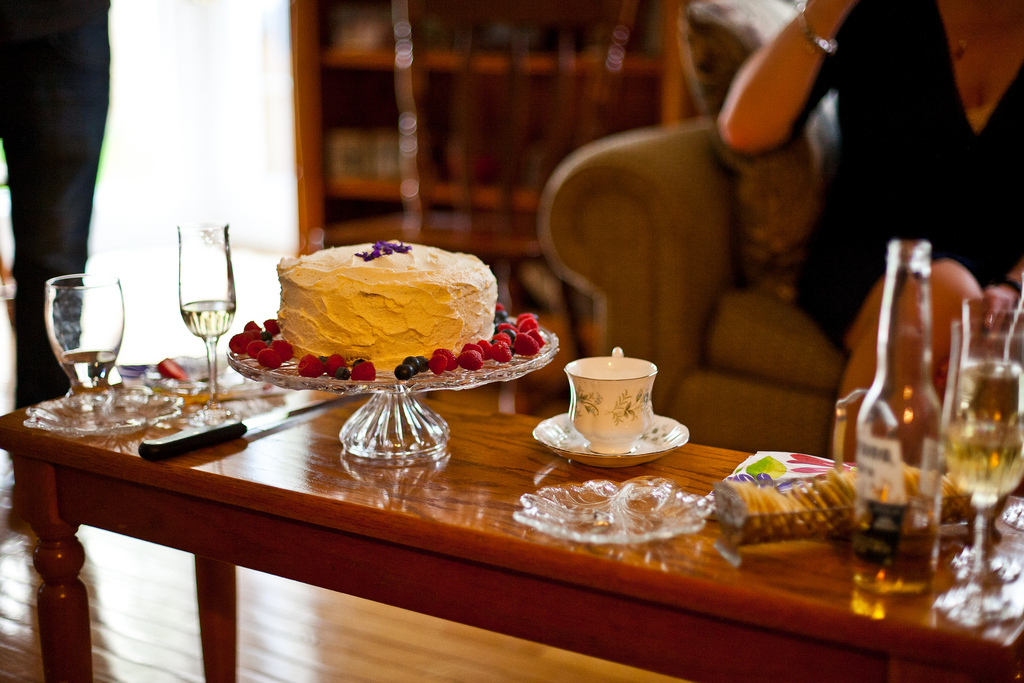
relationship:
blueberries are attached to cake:
[353, 239, 411, 263] [219, 217, 520, 390]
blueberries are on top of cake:
[353, 239, 411, 263] [219, 217, 520, 390]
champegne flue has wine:
[176, 220, 242, 430] [169, 278, 250, 356]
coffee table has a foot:
[0, 377, 1024, 683] [4, 410, 108, 678]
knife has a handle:
[139, 393, 375, 463] [141, 410, 256, 477]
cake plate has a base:
[220, 293, 571, 479] [311, 388, 487, 479]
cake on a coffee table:
[242, 209, 526, 397] [0, 377, 1024, 683]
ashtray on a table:
[482, 412, 742, 618] [0, 248, 1018, 646]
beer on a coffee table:
[851, 239, 949, 600] [0, 377, 1024, 683]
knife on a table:
[139, 393, 375, 463] [35, 289, 1016, 620]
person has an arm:
[718, 0, 1022, 467] [640, 0, 867, 215]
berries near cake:
[225, 316, 561, 396] [251, 209, 506, 389]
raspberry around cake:
[346, 345, 383, 412] [236, 226, 511, 408]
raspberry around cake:
[290, 345, 317, 389] [242, 209, 526, 397]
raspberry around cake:
[253, 336, 288, 380] [257, 230, 519, 373]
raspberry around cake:
[458, 336, 497, 378] [197, 135, 547, 382]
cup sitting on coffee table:
[562, 346, 658, 454] [0, 377, 1024, 683]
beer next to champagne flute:
[851, 239, 949, 600] [923, 237, 1019, 672]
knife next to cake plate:
[119, 388, 340, 486] [225, 316, 559, 461]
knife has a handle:
[139, 393, 375, 463] [127, 408, 249, 484]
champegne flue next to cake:
[156, 200, 234, 419] [257, 230, 519, 373]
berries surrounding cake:
[225, 316, 561, 396] [259, 187, 525, 393]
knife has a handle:
[139, 393, 375, 463] [138, 403, 244, 492]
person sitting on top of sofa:
[741, 9, 996, 409] [544, 42, 1020, 438]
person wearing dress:
[718, 0, 1022, 467] [783, 3, 1021, 362]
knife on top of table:
[139, 393, 375, 463] [35, 273, 1021, 656]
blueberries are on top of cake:
[335, 223, 429, 278] [269, 223, 496, 360]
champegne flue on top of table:
[176, 220, 242, 430] [35, 273, 1021, 656]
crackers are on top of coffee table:
[716, 461, 866, 568] [0, 377, 1024, 683]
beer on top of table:
[839, 227, 950, 636] [35, 273, 1021, 656]